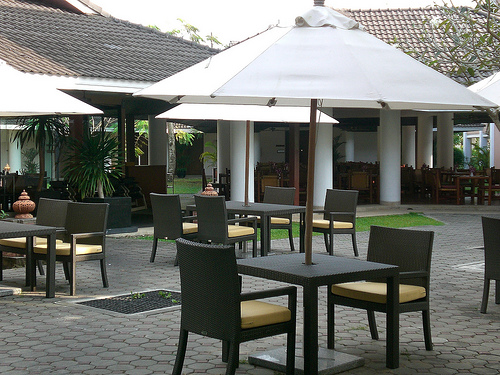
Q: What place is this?
A: It is a cafe.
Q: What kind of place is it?
A: It is a cafe.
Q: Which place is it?
A: It is a cafe.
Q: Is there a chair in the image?
A: Yes, there is a chair.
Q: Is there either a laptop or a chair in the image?
A: Yes, there is a chair.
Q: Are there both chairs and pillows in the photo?
A: No, there is a chair but no pillows.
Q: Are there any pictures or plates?
A: No, there are no plates or pictures.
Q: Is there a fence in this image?
A: No, there are no fences.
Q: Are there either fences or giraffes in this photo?
A: No, there are no fences or giraffes.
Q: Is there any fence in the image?
A: No, there are no fences.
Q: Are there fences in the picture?
A: No, there are no fences.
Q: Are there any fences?
A: No, there are no fences.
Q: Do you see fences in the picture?
A: No, there are no fences.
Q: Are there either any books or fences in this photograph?
A: No, there are no fences or books.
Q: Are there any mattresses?
A: No, there are no mattresses.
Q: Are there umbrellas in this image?
A: Yes, there is an umbrella.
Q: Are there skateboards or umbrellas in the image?
A: Yes, there is an umbrella.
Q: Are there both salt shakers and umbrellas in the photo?
A: No, there is an umbrella but no salt shakers.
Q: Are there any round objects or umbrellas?
A: Yes, there is a round umbrella.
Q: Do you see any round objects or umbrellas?
A: Yes, there is a round umbrella.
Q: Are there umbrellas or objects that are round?
A: Yes, the umbrella is round.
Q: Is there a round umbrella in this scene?
A: Yes, there is a round umbrella.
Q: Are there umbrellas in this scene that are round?
A: Yes, there is an umbrella that is round.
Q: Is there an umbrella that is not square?
A: Yes, there is a round umbrella.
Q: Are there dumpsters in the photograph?
A: No, there are no dumpsters.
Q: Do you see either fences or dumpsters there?
A: No, there are no dumpsters or fences.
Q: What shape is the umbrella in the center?
A: The umbrella is round.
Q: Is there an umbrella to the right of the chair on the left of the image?
A: Yes, there is an umbrella to the right of the chair.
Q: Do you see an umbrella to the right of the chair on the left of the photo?
A: Yes, there is an umbrella to the right of the chair.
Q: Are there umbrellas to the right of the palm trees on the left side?
A: Yes, there is an umbrella to the right of the palm trees.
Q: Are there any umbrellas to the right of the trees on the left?
A: Yes, there is an umbrella to the right of the palm trees.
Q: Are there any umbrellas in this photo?
A: Yes, there is an umbrella.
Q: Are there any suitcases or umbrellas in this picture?
A: Yes, there is an umbrella.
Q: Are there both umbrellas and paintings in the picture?
A: No, there is an umbrella but no paintings.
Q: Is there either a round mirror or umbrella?
A: Yes, there is a round umbrella.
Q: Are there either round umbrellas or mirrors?
A: Yes, there is a round umbrella.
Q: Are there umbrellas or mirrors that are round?
A: Yes, the umbrella is round.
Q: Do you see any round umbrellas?
A: Yes, there is a round umbrella.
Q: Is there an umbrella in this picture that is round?
A: Yes, there is an umbrella that is round.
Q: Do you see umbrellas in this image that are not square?
A: Yes, there is a round umbrella.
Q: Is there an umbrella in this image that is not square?
A: Yes, there is a round umbrella.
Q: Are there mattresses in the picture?
A: No, there are no mattresses.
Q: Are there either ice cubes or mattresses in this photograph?
A: No, there are no mattresses or ice cubes.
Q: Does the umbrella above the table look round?
A: Yes, the umbrella is round.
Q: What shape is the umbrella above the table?
A: The umbrella is round.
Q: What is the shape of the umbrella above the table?
A: The umbrella is round.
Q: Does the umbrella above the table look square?
A: No, the umbrella is round.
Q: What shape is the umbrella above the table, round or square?
A: The umbrella is round.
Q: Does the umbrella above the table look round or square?
A: The umbrella is round.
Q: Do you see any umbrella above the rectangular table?
A: Yes, there is an umbrella above the table.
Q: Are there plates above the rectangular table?
A: No, there is an umbrella above the table.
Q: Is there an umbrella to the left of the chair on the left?
A: No, the umbrella is to the right of the chair.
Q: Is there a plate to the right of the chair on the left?
A: No, there is an umbrella to the right of the chair.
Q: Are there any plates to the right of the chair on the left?
A: No, there is an umbrella to the right of the chair.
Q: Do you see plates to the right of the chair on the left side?
A: No, there is an umbrella to the right of the chair.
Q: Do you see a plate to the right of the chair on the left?
A: No, there is an umbrella to the right of the chair.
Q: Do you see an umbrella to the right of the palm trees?
A: Yes, there is an umbrella to the right of the palm trees.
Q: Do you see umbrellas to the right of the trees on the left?
A: Yes, there is an umbrella to the right of the palm trees.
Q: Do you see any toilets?
A: No, there are no toilets.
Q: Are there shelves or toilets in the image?
A: No, there are no toilets or shelves.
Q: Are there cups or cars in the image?
A: No, there are no cars or cups.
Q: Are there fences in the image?
A: No, there are no fences.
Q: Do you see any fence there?
A: No, there are no fences.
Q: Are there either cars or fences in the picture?
A: No, there are no fences or cars.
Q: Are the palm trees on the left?
A: Yes, the palm trees are on the left of the image.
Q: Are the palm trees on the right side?
A: No, the palm trees are on the left of the image.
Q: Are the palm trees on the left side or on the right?
A: The palm trees are on the left of the image.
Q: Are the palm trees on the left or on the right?
A: The palm trees are on the left of the image.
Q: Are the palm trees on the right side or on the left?
A: The palm trees are on the left of the image.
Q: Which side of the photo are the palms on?
A: The palms are on the left of the image.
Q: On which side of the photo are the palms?
A: The palms are on the left of the image.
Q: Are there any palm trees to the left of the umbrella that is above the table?
A: Yes, there are palm trees to the left of the umbrella.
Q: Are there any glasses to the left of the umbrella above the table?
A: No, there are palm trees to the left of the umbrella.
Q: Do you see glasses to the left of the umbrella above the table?
A: No, there are palm trees to the left of the umbrella.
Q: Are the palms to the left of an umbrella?
A: Yes, the palms are to the left of an umbrella.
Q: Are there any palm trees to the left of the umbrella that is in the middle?
A: Yes, there are palm trees to the left of the umbrella.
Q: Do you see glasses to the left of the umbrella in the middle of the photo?
A: No, there are palm trees to the left of the umbrella.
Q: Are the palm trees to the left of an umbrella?
A: Yes, the palm trees are to the left of an umbrella.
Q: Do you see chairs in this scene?
A: Yes, there is a chair.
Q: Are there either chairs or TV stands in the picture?
A: Yes, there is a chair.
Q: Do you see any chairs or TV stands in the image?
A: Yes, there is a chair.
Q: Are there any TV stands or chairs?
A: Yes, there is a chair.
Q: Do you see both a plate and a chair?
A: No, there is a chair but no plates.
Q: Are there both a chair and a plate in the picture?
A: No, there is a chair but no plates.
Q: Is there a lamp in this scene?
A: No, there are no lamps.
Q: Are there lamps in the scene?
A: No, there are no lamps.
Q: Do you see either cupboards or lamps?
A: No, there are no lamps or cupboards.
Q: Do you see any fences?
A: No, there are no fences.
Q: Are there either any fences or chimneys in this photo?
A: No, there are no fences or chimneys.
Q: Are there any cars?
A: No, there are no cars.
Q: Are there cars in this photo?
A: No, there are no cars.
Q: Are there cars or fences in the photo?
A: No, there are no cars or fences.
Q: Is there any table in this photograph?
A: Yes, there is a table.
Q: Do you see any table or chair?
A: Yes, there is a table.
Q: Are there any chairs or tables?
A: Yes, there is a table.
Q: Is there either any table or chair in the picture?
A: Yes, there is a table.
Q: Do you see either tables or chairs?
A: Yes, there is a table.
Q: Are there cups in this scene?
A: No, there are no cups.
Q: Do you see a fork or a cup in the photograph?
A: No, there are no cups or forks.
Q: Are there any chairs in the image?
A: Yes, there is a chair.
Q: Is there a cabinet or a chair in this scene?
A: Yes, there is a chair.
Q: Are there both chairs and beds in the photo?
A: No, there is a chair but no beds.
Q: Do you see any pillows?
A: No, there are no pillows.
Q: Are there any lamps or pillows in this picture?
A: No, there are no pillows or lamps.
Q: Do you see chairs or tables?
A: Yes, there is a chair.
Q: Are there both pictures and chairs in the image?
A: No, there is a chair but no pictures.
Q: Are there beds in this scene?
A: No, there are no beds.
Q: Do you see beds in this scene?
A: No, there are no beds.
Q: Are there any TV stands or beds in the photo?
A: No, there are no beds or TV stands.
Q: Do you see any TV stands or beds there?
A: No, there are no beds or TV stands.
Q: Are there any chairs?
A: Yes, there is a chair.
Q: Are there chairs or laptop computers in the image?
A: Yes, there is a chair.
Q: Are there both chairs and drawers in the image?
A: No, there is a chair but no drawers.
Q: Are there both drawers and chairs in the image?
A: No, there is a chair but no drawers.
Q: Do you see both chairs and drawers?
A: No, there is a chair but no drawers.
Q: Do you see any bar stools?
A: No, there are no bar stools.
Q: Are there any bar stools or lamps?
A: No, there are no bar stools or lamps.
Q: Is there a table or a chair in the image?
A: Yes, there is a chair.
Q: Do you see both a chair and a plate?
A: No, there is a chair but no plates.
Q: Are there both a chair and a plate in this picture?
A: No, there is a chair but no plates.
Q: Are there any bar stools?
A: No, there are no bar stools.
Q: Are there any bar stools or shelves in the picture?
A: No, there are no bar stools or shelves.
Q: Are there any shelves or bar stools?
A: No, there are no bar stools or shelves.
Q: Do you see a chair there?
A: Yes, there is a chair.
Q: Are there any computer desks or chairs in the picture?
A: Yes, there is a chair.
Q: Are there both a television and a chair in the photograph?
A: No, there is a chair but no televisions.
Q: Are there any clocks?
A: No, there are no clocks.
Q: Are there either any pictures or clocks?
A: No, there are no clocks or pictures.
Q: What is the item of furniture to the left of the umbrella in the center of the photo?
A: The piece of furniture is a chair.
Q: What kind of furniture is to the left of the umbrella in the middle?
A: The piece of furniture is a chair.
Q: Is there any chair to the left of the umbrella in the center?
A: Yes, there is a chair to the left of the umbrella.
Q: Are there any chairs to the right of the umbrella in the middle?
A: No, the chair is to the left of the umbrella.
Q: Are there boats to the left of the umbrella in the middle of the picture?
A: No, there is a chair to the left of the umbrella.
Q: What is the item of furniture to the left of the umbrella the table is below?
A: The piece of furniture is a chair.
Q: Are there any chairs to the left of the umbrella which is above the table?
A: Yes, there is a chair to the left of the umbrella.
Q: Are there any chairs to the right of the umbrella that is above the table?
A: No, the chair is to the left of the umbrella.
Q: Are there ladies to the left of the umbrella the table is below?
A: No, there is a chair to the left of the umbrella.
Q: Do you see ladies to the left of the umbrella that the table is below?
A: No, there is a chair to the left of the umbrella.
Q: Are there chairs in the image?
A: Yes, there is a chair.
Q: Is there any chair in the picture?
A: Yes, there is a chair.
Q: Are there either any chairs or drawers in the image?
A: Yes, there is a chair.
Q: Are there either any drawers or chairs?
A: Yes, there is a chair.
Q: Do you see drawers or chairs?
A: Yes, there is a chair.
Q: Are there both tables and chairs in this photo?
A: Yes, there are both a chair and a table.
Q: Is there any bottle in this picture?
A: No, there are no bottles.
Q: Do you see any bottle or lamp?
A: No, there are no bottles or lamps.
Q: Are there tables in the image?
A: Yes, there is a table.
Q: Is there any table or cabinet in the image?
A: Yes, there is a table.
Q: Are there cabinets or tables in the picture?
A: Yes, there is a table.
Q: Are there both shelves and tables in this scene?
A: No, there is a table but no shelves.